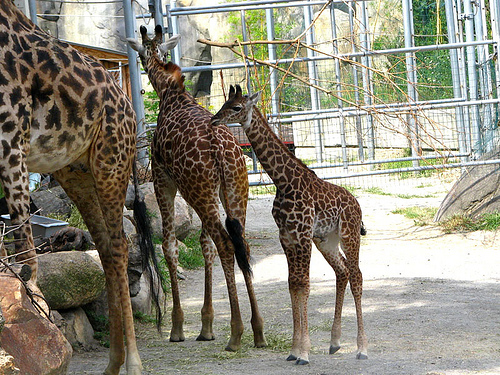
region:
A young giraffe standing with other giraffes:
[207, 64, 371, 374]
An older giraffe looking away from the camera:
[117, 16, 277, 369]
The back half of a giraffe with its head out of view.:
[0, 5, 135, 374]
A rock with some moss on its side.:
[37, 227, 99, 351]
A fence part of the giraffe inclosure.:
[152, 2, 495, 180]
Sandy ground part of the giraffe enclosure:
[142, 165, 497, 374]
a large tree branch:
[202, 35, 377, 92]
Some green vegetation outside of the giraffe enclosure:
[249, 7, 443, 107]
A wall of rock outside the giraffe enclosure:
[35, 4, 495, 92]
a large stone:
[432, 152, 497, 227]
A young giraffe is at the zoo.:
[210, 44, 493, 369]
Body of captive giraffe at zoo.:
[0, 43, 150, 373]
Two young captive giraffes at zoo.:
[137, 4, 496, 371]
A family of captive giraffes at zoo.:
[2, 1, 406, 373]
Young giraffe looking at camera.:
[210, 90, 425, 372]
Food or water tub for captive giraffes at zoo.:
[2, 213, 92, 248]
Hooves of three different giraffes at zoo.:
[111, 321, 366, 372]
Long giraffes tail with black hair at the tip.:
[220, 165, 270, 298]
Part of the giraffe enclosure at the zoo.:
[315, 42, 496, 181]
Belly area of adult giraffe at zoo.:
[16, 42, 103, 177]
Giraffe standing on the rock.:
[2, 4, 140, 371]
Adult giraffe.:
[124, 20, 254, 351]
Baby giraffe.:
[210, 78, 375, 367]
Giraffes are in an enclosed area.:
[3, 2, 498, 369]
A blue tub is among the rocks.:
[1, 198, 70, 244]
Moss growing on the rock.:
[28, 247, 111, 319]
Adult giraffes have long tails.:
[4, 2, 256, 362]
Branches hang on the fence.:
[191, 7, 463, 167]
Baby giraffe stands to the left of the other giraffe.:
[127, 17, 383, 364]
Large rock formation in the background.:
[40, 1, 228, 121]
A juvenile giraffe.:
[215, 85, 403, 373]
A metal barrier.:
[278, 12, 497, 164]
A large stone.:
[424, 131, 499, 220]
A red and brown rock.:
[2, 270, 77, 372]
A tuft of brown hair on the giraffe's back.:
[162, 59, 188, 92]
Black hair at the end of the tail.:
[215, 210, 266, 281]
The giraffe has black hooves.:
[278, 341, 384, 370]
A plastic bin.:
[0, 210, 69, 235]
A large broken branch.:
[187, 15, 472, 98]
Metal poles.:
[456, 6, 493, 103]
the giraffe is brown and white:
[220, 94, 395, 362]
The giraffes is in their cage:
[78, 25, 384, 359]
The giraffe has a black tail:
[225, 214, 274, 287]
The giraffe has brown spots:
[279, 151, 366, 234]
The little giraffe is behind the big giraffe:
[140, 34, 360, 372]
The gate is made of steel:
[293, 10, 493, 180]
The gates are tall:
[310, 46, 485, 191]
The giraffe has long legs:
[58, 158, 179, 363]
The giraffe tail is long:
[125, 177, 180, 330]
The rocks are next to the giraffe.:
[41, 211, 183, 322]